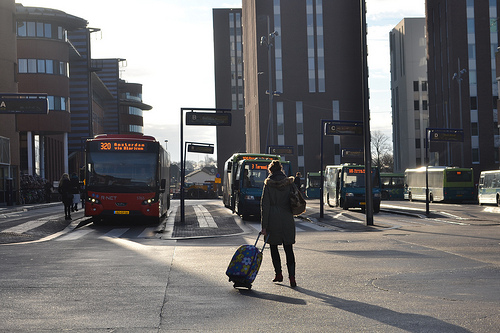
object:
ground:
[0, 195, 500, 333]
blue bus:
[322, 162, 382, 214]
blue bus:
[233, 159, 292, 219]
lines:
[54, 229, 97, 242]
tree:
[370, 130, 393, 172]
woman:
[259, 160, 299, 288]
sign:
[428, 132, 465, 143]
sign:
[324, 123, 364, 136]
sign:
[186, 112, 233, 126]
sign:
[188, 145, 214, 155]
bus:
[78, 132, 170, 226]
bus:
[402, 165, 478, 203]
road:
[0, 199, 500, 330]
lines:
[197, 204, 219, 228]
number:
[101, 142, 105, 150]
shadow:
[271, 282, 474, 333]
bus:
[477, 168, 500, 207]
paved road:
[0, 225, 500, 333]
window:
[332, 99, 340, 120]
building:
[240, 0, 371, 199]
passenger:
[58, 172, 75, 221]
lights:
[147, 198, 151, 203]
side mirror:
[161, 178, 167, 189]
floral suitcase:
[225, 231, 272, 290]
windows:
[57, 26, 63, 39]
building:
[15, 3, 88, 205]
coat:
[260, 170, 304, 246]